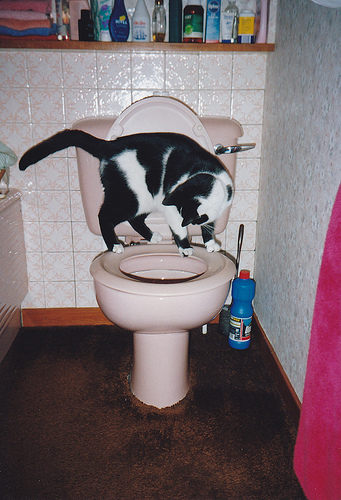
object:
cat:
[18, 129, 235, 258]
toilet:
[75, 90, 244, 410]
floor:
[1, 304, 307, 500]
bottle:
[227, 269, 256, 350]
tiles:
[0, 49, 265, 308]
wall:
[0, 0, 341, 415]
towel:
[293, 184, 341, 499]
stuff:
[0, 0, 267, 43]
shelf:
[0, 40, 275, 52]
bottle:
[110, 0, 129, 42]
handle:
[213, 143, 255, 155]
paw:
[205, 239, 221, 253]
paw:
[150, 231, 163, 244]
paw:
[179, 247, 194, 258]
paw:
[112, 243, 124, 254]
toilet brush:
[218, 224, 244, 335]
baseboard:
[130, 330, 190, 409]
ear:
[162, 188, 176, 206]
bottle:
[132, 0, 151, 42]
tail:
[18, 129, 106, 171]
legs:
[99, 219, 127, 254]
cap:
[240, 269, 250, 279]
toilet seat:
[89, 244, 237, 296]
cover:
[105, 97, 217, 245]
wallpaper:
[253, 4, 341, 408]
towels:
[0, 0, 58, 39]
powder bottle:
[237, 9, 255, 44]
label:
[237, 16, 254, 36]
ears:
[182, 217, 193, 227]